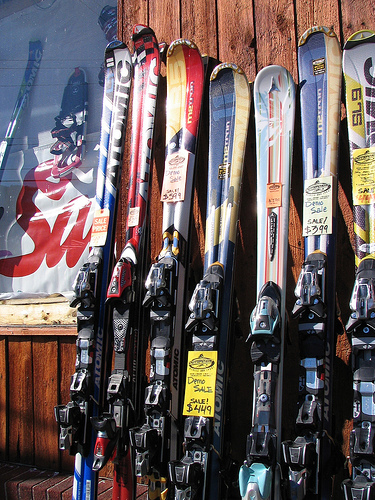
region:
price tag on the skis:
[186, 357, 215, 419]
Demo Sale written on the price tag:
[191, 375, 210, 395]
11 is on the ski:
[209, 89, 243, 119]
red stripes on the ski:
[267, 95, 280, 286]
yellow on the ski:
[164, 51, 183, 125]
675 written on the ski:
[348, 89, 366, 131]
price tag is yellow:
[188, 347, 217, 415]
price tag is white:
[302, 178, 334, 235]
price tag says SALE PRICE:
[95, 217, 109, 237]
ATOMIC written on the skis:
[107, 59, 130, 191]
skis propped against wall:
[44, 29, 363, 491]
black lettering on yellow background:
[179, 346, 219, 415]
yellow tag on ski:
[177, 344, 225, 419]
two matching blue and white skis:
[187, 33, 345, 499]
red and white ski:
[111, 20, 157, 493]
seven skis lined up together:
[58, 25, 374, 499]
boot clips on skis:
[56, 248, 374, 489]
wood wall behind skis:
[7, 9, 373, 461]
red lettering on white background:
[2, 164, 85, 277]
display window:
[1, 4, 88, 335]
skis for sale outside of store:
[58, 25, 373, 499]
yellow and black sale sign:
[181, 348, 217, 417]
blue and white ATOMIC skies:
[53, 36, 131, 499]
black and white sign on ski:
[300, 174, 333, 236]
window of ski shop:
[0, 1, 114, 294]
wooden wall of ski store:
[1, 336, 75, 472]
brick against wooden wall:
[0, 457, 148, 498]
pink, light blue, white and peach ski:
[235, 63, 296, 498]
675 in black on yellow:
[350, 83, 361, 128]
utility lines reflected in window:
[1, 55, 103, 88]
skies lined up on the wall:
[37, 14, 370, 499]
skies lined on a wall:
[55, 32, 354, 497]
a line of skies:
[66, 14, 374, 485]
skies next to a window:
[33, 10, 374, 423]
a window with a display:
[18, 12, 147, 390]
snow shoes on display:
[22, 25, 172, 238]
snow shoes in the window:
[25, 36, 175, 239]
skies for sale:
[62, 35, 341, 496]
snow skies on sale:
[32, 42, 342, 498]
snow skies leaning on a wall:
[47, 51, 336, 496]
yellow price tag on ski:
[181, 348, 219, 418]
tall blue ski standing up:
[54, 37, 133, 498]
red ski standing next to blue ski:
[89, 20, 165, 498]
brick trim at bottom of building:
[0, 460, 151, 498]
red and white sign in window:
[0, 128, 105, 298]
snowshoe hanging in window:
[48, 63, 91, 178]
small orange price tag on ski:
[263, 179, 284, 208]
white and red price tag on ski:
[88, 208, 110, 246]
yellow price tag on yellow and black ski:
[351, 145, 374, 203]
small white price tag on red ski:
[125, 206, 140, 229]